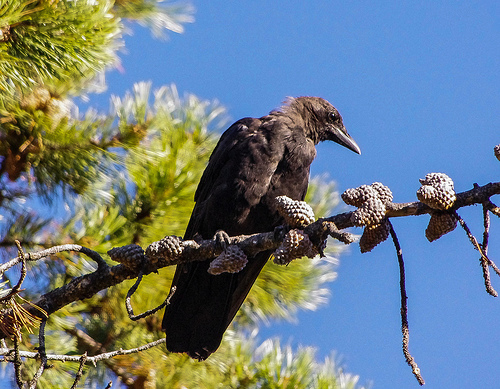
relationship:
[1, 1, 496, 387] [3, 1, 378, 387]
tree has leaves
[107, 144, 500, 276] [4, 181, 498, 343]
pine cones on branch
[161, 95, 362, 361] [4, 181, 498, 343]
bird sitting on branch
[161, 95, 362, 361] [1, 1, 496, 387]
bird sitting on tree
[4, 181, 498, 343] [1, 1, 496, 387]
branch on tree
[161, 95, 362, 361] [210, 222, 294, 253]
bird has feet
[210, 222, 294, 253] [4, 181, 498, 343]
feet grasping branch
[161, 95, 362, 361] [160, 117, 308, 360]
bird has wing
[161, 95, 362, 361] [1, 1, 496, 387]
bird perched on tree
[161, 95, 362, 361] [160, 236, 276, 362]
bird has tail feathers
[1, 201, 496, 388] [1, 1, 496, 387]
twigs on tree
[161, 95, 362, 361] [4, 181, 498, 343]
bird on branch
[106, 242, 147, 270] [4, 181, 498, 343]
pine cone on branch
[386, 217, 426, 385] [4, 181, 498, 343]
twig sticking off branch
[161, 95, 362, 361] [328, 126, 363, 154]
bird has beak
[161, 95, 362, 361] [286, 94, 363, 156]
bird has head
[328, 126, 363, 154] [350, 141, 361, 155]
beak has tip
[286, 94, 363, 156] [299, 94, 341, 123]
head has top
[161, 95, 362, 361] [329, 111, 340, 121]
bird has eye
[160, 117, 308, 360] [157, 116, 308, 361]
wing has feathers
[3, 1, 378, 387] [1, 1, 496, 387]
leaves on tree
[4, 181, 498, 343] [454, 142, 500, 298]
branch has tip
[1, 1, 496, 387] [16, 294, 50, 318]
tree has leaf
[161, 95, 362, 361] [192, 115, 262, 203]
bird has feather